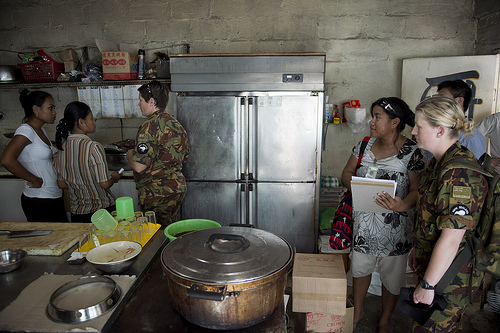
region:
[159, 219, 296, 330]
A pot sitting on the stove.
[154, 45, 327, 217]
A metal fridge sitting in the background.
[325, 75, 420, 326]
A woman holding a note pad.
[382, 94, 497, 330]
A soldier watching others.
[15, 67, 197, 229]
A soldier getting cooking lessons.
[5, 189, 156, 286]
Some dirty dishes to the side.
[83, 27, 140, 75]
A box on a shelf.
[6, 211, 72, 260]
A knife on a cutting board.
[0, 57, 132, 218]
Two girls cooking.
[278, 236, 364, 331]
Boxes stacked on the floor.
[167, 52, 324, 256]
Beat up industrial refrigerator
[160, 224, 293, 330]
Huge, filthy cooking pot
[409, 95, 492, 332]
Woman with short blonde hair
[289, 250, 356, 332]
Two cardboard boxes stacked on top of each other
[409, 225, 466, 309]
A woman's arm with a wristwatch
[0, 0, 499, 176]
A dirty cement wall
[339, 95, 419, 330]
A woman with a black and white top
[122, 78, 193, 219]
Person wearing camoflauge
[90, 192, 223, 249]
Bright green containers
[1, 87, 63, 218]
Woman wearing a white t shirt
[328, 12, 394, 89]
grey cinder block brick wall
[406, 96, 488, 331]
blond woman in army uniform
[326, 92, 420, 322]
woman in a black and white top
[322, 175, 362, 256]
woman's red and black purse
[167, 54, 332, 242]
stainless steel refrigerator and freezer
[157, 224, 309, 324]
large cooking pot with lid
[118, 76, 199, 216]
brunette woman in army uniform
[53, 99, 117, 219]
woman in striped shirt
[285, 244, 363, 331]
stacked brown cardboard boxes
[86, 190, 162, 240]
drinking glasses on counter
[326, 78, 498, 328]
People standing in kitchen.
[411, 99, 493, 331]
Woman in kitchen dressed in camouflage outfit.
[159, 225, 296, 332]
Huge pot sitting on table.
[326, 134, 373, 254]
Woman wearing black and red purse over shoulder.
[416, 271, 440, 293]
Woman wearing watch on left wrist.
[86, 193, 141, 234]
Green plastic cups turned down over clear water glasses.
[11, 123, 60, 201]
Woman dressed in white vee neck top.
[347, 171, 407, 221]
Woman holding paper tablet in hand.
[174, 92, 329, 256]
Silver refrigerator against wall in kitchen.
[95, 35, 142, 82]
Brown and red cardboard box sitting on shelf in kitchen.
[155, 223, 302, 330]
large kitchen pot with lid on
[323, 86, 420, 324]
woman holding a pad of paper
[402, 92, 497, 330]
blond woman in camoflage uniform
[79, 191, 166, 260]
glass cups drying on a yellow tray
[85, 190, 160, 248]
green cups stacked on clear glasses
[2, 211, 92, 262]
a knife on a cutting board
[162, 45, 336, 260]
refrigerator with double door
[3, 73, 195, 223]
woman in camoflage uniform instructing two workers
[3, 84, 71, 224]
woman in white t-shirt with her hand on her hip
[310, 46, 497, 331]
group of people standing near the open door